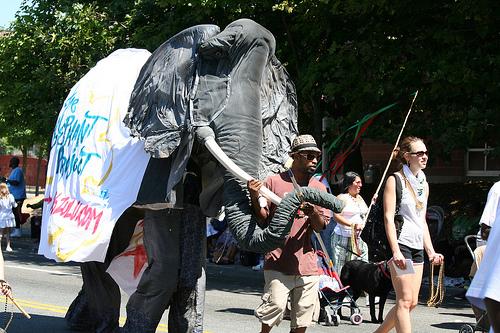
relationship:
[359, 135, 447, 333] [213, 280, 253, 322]
girl walking down street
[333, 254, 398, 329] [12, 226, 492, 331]
black dog on street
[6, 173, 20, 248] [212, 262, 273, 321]
child on street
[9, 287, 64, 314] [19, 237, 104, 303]
line on street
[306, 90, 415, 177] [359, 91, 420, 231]
streamer flying from pole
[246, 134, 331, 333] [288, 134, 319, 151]
guy wearing hat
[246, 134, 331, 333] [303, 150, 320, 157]
guy wearing sunglasses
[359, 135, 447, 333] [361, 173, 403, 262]
girl carrying black bag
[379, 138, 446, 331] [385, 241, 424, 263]
girl wearing black shorts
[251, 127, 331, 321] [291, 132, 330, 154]
guy wearing hat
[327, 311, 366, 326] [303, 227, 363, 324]
front wheels of stroller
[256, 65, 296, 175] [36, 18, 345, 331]
left ear of elephant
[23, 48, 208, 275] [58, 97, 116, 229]
banner with letters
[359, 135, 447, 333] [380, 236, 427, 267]
girl in black shorts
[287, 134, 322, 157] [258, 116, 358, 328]
hat on man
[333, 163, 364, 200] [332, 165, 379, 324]
hair on woman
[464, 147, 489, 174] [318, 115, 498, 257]
window of building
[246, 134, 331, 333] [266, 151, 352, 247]
guy has shirt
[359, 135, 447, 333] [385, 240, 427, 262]
girl has black shorts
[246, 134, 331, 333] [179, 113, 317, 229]
guy holding tusk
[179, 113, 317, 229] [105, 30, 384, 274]
tusk of elephant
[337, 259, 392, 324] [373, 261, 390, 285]
black dog wearing collar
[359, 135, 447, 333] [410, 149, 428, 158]
girl wearing sunglasses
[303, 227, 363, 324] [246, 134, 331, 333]
stroller next to guy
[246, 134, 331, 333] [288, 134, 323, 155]
guy has hat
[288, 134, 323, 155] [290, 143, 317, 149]
hat has stripe